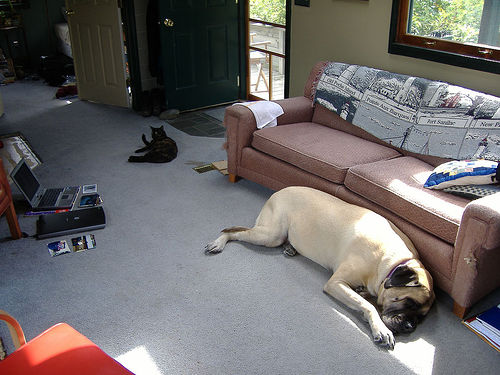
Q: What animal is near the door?
A: Cat.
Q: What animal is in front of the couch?
A: Dog.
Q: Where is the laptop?
A: On floor to the left.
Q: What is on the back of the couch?
A: Blanket.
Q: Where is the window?
A: Above couch.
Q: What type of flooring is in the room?
A: Carpeting.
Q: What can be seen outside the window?
A: Trees.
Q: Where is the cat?
A: Near door.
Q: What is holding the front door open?
A: Rock.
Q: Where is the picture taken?
A: A living room.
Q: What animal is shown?
A: A dog.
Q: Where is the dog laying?
A: The floor.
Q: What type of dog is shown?
A: A mastiff.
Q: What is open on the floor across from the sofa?
A: A laptop.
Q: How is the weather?
A: Sunny.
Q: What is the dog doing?
A: Sleeping.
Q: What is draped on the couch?
A: A throw.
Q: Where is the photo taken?
A: Living Room.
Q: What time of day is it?
A: Daytime.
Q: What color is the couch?
A: Mauve.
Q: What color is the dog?
A: White.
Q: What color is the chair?
A: Orange.